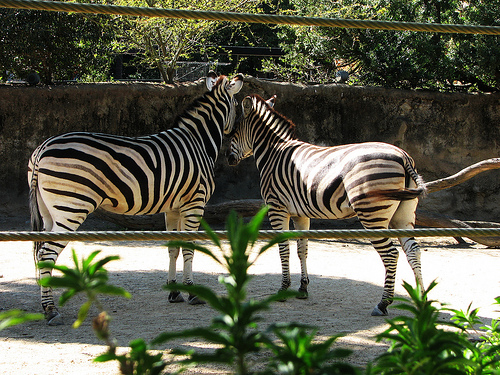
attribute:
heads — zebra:
[202, 72, 284, 167]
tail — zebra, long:
[21, 153, 51, 295]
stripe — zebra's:
[66, 134, 151, 212]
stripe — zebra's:
[140, 132, 165, 209]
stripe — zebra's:
[163, 129, 183, 206]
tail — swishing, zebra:
[387, 143, 442, 211]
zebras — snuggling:
[18, 23, 495, 343]